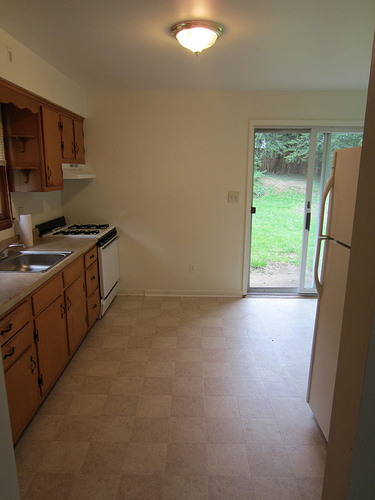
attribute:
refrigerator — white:
[305, 171, 367, 416]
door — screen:
[253, 136, 304, 293]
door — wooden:
[33, 297, 76, 389]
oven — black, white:
[33, 215, 123, 320]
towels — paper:
[18, 209, 36, 248]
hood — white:
[61, 161, 97, 181]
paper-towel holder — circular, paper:
[13, 204, 29, 223]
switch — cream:
[226, 182, 238, 202]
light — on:
[168, 18, 225, 56]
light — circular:
[161, 7, 254, 56]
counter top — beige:
[72, 234, 96, 244]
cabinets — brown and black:
[0, 78, 84, 229]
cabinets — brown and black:
[1, 243, 101, 447]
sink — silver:
[0, 250, 69, 270]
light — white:
[164, 10, 255, 65]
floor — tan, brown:
[115, 285, 275, 485]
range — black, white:
[34, 214, 121, 316]